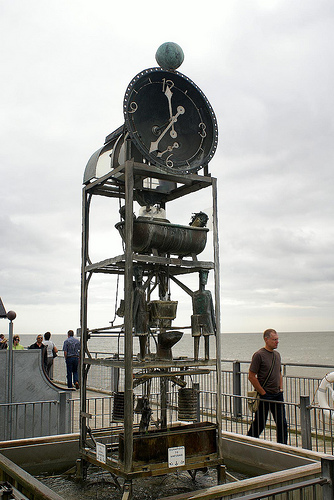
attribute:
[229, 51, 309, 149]
sky — full, clouds, overcast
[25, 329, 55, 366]
lady — wearing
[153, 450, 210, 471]
sign — black, white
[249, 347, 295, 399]
strap — here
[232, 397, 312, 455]
railing — around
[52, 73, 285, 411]
structure — metal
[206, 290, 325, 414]
man — walking, wearing, here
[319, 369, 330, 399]
preserver — attached, white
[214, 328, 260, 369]
water — calm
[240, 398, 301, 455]
pants — black, pair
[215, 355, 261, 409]
fence — grey, metal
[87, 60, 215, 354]
tower — here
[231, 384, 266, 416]
bag — here, canvas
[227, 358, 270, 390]
elbow — here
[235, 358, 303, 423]
arm — here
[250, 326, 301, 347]
head — here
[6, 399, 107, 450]
enclosure — metal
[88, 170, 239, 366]
statue — metal, person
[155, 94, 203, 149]
hands — white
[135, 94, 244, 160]
number — white, 6, 9, 12